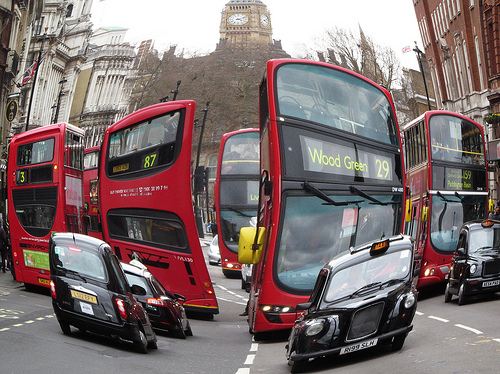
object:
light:
[404, 296, 415, 309]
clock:
[228, 14, 249, 26]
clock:
[260, 14, 269, 27]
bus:
[214, 127, 265, 280]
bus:
[401, 110, 490, 290]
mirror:
[238, 226, 267, 264]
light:
[307, 322, 324, 336]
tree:
[131, 25, 408, 112]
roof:
[259, 57, 389, 91]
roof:
[400, 109, 483, 127]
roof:
[106, 100, 194, 129]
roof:
[11, 122, 85, 138]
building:
[217, 1, 288, 50]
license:
[481, 279, 499, 286]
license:
[38, 278, 49, 285]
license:
[71, 290, 98, 305]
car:
[444, 219, 498, 306]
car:
[284, 232, 419, 373]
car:
[118, 259, 193, 339]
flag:
[16, 51, 52, 88]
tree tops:
[143, 24, 370, 49]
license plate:
[79, 301, 94, 316]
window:
[325, 249, 412, 303]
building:
[316, 1, 500, 213]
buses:
[6, 56, 498, 374]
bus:
[97, 100, 220, 322]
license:
[340, 338, 379, 356]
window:
[455, 44, 470, 94]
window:
[441, 58, 459, 101]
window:
[428, 58, 443, 109]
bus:
[6, 122, 87, 290]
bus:
[237, 58, 411, 342]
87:
[144, 154, 157, 168]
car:
[49, 216, 158, 354]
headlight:
[260, 304, 297, 314]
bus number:
[308, 146, 390, 178]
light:
[115, 298, 128, 319]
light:
[49, 280, 57, 300]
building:
[0, 0, 161, 173]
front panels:
[3, 63, 415, 316]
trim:
[420, 4, 470, 100]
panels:
[223, 4, 258, 38]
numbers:
[230, 14, 247, 24]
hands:
[264, 20, 268, 23]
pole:
[192, 101, 210, 238]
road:
[0, 273, 500, 374]